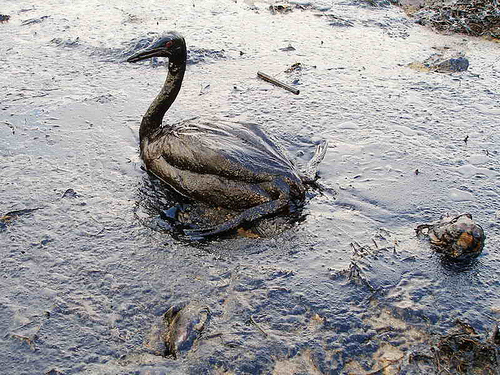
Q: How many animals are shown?
A: One.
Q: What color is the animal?
A: Black.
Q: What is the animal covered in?
A: Oil.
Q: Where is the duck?
A: On water.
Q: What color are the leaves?
A: Brown.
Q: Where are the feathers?
A: On duck.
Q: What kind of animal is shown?
A: Duck.